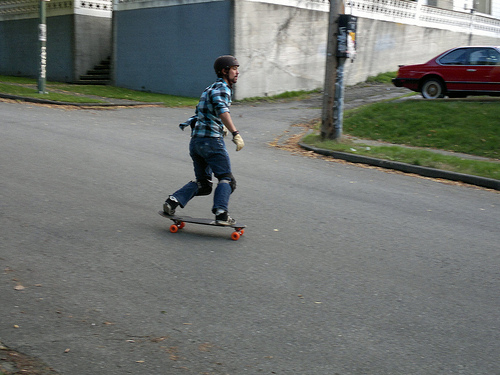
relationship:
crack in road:
[125, 330, 153, 342] [1, 98, 500, 374]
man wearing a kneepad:
[161, 55, 246, 224] [212, 170, 241, 193]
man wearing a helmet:
[161, 55, 246, 224] [213, 53, 240, 82]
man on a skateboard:
[161, 55, 246, 224] [156, 205, 247, 239]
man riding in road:
[161, 55, 246, 224] [1, 98, 500, 374]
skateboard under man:
[156, 205, 247, 239] [161, 55, 246, 224]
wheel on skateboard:
[227, 229, 241, 242] [156, 205, 247, 239]